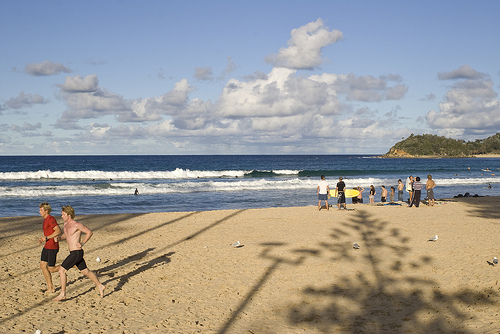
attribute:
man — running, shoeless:
[33, 199, 66, 296]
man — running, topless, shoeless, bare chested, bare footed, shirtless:
[55, 204, 107, 302]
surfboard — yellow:
[326, 188, 361, 198]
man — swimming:
[132, 187, 139, 197]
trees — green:
[406, 129, 498, 154]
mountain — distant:
[379, 131, 497, 160]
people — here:
[314, 172, 438, 207]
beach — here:
[2, 200, 498, 332]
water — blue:
[4, 151, 500, 212]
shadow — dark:
[299, 206, 464, 333]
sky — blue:
[2, 3, 496, 159]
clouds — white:
[270, 17, 342, 74]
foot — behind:
[98, 283, 107, 298]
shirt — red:
[41, 214, 59, 249]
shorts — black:
[62, 248, 87, 270]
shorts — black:
[40, 245, 59, 267]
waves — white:
[2, 169, 311, 178]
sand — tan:
[2, 201, 500, 332]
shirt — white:
[318, 179, 329, 195]